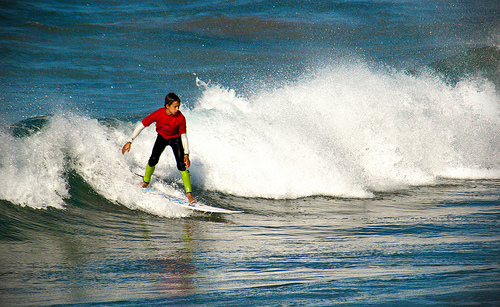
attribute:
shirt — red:
[140, 108, 191, 140]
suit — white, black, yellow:
[125, 103, 205, 196]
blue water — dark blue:
[224, 189, 450, 248]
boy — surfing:
[121, 91, 198, 205]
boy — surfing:
[117, 86, 242, 238]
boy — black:
[85, 73, 316, 244]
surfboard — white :
[117, 157, 287, 229]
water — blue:
[11, 176, 106, 248]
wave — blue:
[4, 63, 487, 210]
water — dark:
[272, 225, 375, 286]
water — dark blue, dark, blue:
[3, 8, 492, 298]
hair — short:
[163, 90, 183, 110]